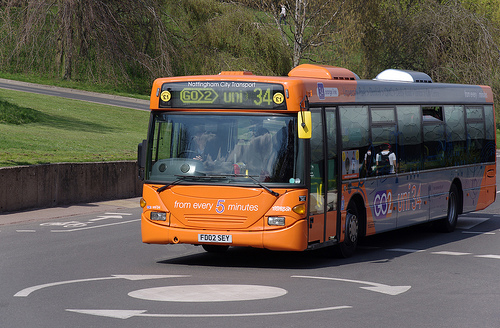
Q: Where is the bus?
A: A roundabout.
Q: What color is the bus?
A: Orange.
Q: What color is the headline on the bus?
A: Green.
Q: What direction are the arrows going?
A: Clockwise.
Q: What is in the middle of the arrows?
A: A circle.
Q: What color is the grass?
A: Green.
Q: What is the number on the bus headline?
A: 34.